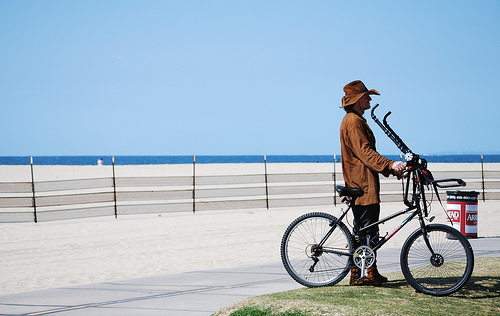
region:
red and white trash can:
[438, 176, 484, 241]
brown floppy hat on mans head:
[332, 71, 384, 119]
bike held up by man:
[267, 169, 484, 304]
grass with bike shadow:
[373, 267, 483, 313]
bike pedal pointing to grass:
[346, 245, 377, 287]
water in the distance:
[121, 145, 315, 169]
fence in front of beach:
[108, 168, 272, 224]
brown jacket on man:
[338, 106, 375, 211]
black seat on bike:
[328, 180, 370, 202]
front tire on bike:
[388, 214, 482, 301]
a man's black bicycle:
[259, 149, 483, 304]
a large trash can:
[440, 184, 487, 244]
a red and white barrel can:
[441, 184, 486, 247]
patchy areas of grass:
[278, 275, 496, 315]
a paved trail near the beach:
[44, 184, 371, 314]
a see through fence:
[20, 135, 369, 210]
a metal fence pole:
[107, 150, 129, 217]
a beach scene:
[28, 95, 303, 198]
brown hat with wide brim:
[335, 70, 383, 112]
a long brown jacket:
[330, 104, 397, 207]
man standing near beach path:
[65, 73, 480, 294]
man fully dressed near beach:
[266, 70, 477, 300]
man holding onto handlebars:
[275, 140, 480, 291]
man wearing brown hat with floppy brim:
[331, 65, 381, 115]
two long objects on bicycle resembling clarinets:
[365, 95, 435, 187]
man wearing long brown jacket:
[326, 110, 386, 210]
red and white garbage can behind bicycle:
[430, 175, 481, 250]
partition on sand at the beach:
[10, 156, 461, 236]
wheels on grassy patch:
[225, 245, 485, 306]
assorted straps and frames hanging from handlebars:
[382, 152, 467, 218]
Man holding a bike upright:
[277, 61, 481, 300]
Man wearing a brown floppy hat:
[333, 73, 385, 116]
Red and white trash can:
[442, 180, 487, 240]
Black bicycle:
[268, 169, 478, 302]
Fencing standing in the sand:
[17, 150, 287, 218]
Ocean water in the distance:
[16, 139, 326, 169]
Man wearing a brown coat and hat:
[329, 72, 410, 213]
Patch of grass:
[273, 281, 489, 309]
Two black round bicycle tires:
[275, 204, 478, 302]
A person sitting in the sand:
[91, 150, 118, 174]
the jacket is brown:
[337, 120, 377, 196]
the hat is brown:
[335, 81, 380, 98]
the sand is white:
[56, 245, 208, 262]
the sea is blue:
[122, 145, 187, 156]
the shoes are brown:
[345, 255, 392, 282]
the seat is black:
[327, 180, 367, 196]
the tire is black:
[399, 230, 474, 302]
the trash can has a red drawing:
[443, 189, 485, 242]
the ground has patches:
[266, 298, 318, 313]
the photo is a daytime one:
[5, 5, 496, 307]